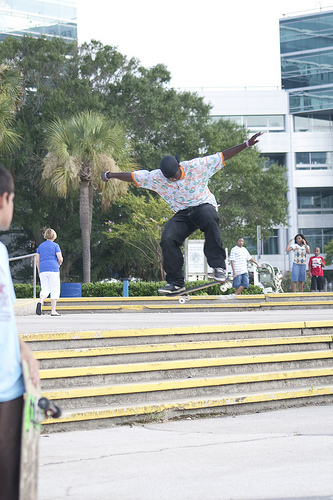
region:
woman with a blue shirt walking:
[29, 225, 71, 317]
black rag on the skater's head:
[155, 152, 187, 178]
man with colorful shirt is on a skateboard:
[96, 126, 279, 304]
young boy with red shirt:
[308, 243, 331, 290]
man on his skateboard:
[97, 130, 276, 305]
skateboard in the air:
[154, 273, 237, 302]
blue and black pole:
[118, 275, 132, 296]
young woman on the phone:
[280, 229, 311, 292]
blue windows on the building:
[277, 8, 332, 53]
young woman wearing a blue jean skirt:
[284, 233, 312, 293]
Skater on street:
[90, 119, 266, 298]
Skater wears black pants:
[86, 120, 289, 301]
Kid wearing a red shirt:
[304, 242, 330, 289]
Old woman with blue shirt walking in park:
[33, 218, 68, 320]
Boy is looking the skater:
[1, 168, 33, 499]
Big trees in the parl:
[8, 34, 295, 283]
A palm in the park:
[41, 110, 139, 287]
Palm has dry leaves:
[37, 103, 139, 289]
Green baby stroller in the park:
[254, 257, 287, 293]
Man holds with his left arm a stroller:
[229, 235, 288, 293]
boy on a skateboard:
[97, 132, 287, 309]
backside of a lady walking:
[27, 223, 68, 327]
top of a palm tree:
[24, 109, 146, 202]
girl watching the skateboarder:
[282, 229, 311, 295]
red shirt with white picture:
[304, 251, 326, 278]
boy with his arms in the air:
[109, 125, 268, 297]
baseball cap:
[155, 153, 183, 181]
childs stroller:
[249, 253, 284, 299]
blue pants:
[152, 202, 234, 286]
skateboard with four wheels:
[171, 276, 239, 307]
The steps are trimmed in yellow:
[62, 333, 326, 428]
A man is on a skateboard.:
[123, 169, 251, 298]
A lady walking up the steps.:
[28, 225, 75, 334]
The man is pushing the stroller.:
[234, 234, 288, 299]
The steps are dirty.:
[119, 349, 319, 425]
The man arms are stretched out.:
[89, 147, 275, 205]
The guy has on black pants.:
[150, 216, 238, 283]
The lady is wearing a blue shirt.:
[30, 239, 70, 276]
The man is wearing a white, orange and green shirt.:
[136, 166, 233, 215]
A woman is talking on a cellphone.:
[289, 234, 314, 290]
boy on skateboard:
[84, 113, 282, 311]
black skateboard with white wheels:
[145, 259, 271, 307]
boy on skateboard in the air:
[69, 115, 284, 320]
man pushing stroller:
[223, 224, 300, 319]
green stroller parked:
[251, 256, 294, 312]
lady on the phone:
[269, 218, 317, 297]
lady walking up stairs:
[31, 212, 66, 323]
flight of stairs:
[25, 313, 332, 420]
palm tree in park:
[27, 102, 128, 299]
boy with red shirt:
[299, 235, 331, 291]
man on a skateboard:
[91, 112, 275, 306]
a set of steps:
[21, 308, 329, 430]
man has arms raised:
[91, 129, 267, 186]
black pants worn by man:
[164, 212, 225, 270]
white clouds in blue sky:
[141, 17, 162, 39]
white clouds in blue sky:
[209, 70, 241, 102]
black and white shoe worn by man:
[158, 277, 182, 297]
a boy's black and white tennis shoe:
[214, 265, 227, 282]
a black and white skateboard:
[157, 276, 238, 307]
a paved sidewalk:
[38, 403, 331, 499]